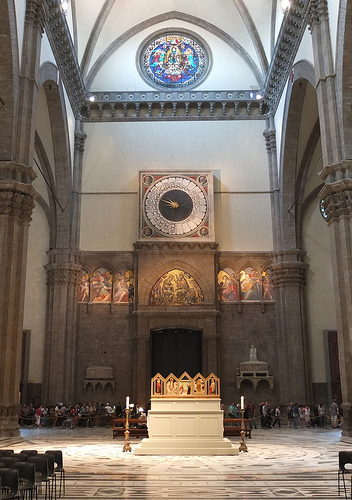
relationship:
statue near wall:
[244, 326, 276, 389] [73, 115, 282, 408]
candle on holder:
[237, 395, 245, 411] [236, 407, 248, 454]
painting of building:
[148, 268, 204, 305] [0, 0, 352, 499]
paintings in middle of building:
[76, 262, 274, 303] [0, 0, 352, 499]